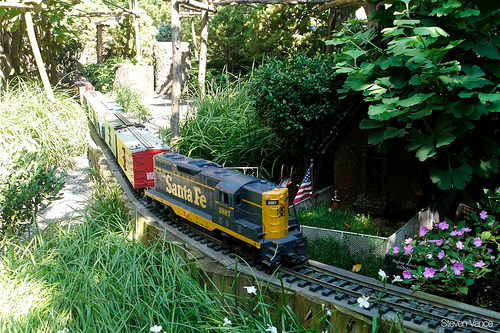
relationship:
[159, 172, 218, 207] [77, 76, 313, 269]
santa fe on side of train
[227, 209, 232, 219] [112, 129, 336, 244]
number painted on engine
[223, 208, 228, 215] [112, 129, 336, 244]
number painted on engine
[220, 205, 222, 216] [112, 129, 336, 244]
number painted on engine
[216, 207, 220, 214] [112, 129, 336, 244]
number painted on engine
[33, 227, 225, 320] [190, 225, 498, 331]
grass growing by tracks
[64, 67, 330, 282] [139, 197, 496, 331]
train on track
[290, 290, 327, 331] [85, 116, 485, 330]
brick supporting track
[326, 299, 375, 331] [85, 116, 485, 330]
brick supporting track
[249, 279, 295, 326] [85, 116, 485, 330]
brick supporting track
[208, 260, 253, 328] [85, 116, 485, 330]
brick supporting track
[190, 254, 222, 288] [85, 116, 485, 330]
brick supporting track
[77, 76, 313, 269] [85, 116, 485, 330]
train riding on track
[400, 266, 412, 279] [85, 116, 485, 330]
flower growing alongside track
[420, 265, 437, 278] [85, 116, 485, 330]
flower growing alongside track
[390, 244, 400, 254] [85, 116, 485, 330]
flower growing alongside track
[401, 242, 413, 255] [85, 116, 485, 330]
flower growing alongside track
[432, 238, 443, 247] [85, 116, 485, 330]
flower growing alongside track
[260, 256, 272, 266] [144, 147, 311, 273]
step leading to engine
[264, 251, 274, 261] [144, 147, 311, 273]
step leading to engine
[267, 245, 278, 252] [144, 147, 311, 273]
step leading to engine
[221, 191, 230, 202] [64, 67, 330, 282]
window built into train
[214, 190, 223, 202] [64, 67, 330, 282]
window built into train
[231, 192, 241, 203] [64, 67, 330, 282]
window built into train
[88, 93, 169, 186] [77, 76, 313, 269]
middle part attached to train